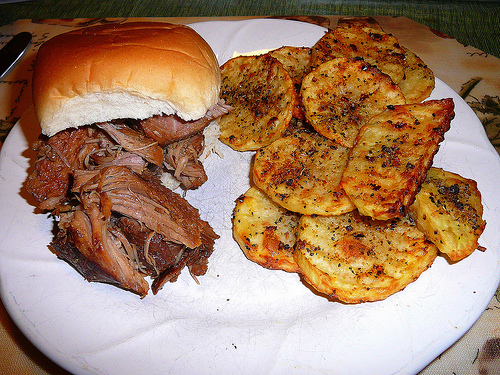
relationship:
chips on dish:
[219, 20, 487, 306] [1, 18, 500, 375]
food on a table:
[17, 21, 488, 305] [8, 11, 499, 374]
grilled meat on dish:
[17, 98, 234, 300] [1, 18, 500, 375]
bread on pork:
[32, 21, 221, 137] [28, 135, 220, 287]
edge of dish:
[401, 288, 485, 364] [1, 18, 500, 375]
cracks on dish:
[174, 138, 279, 263] [1, 18, 500, 375]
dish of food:
[1, 18, 500, 375] [17, 21, 488, 305]